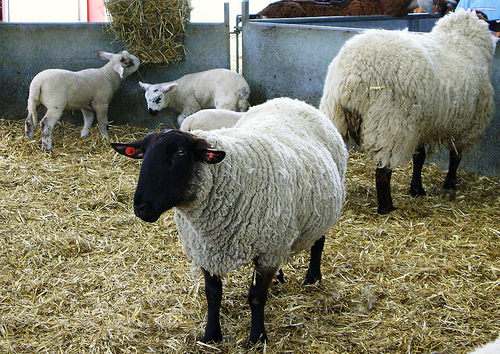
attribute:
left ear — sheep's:
[202, 148, 229, 161]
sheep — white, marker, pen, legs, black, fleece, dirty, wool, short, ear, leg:
[51, 62, 394, 255]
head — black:
[128, 110, 229, 233]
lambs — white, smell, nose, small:
[26, 59, 204, 135]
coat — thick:
[244, 111, 377, 220]